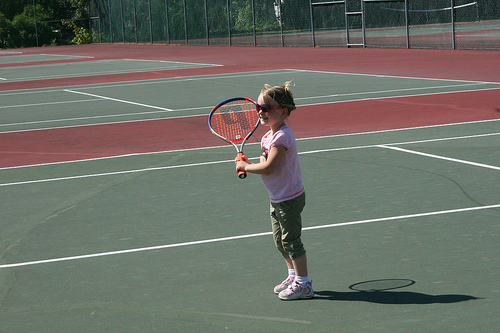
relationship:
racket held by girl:
[206, 97, 263, 179] [245, 70, 329, 305]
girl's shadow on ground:
[292, 267, 482, 316] [4, 39, 494, 324]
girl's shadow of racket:
[312, 289, 481, 305] [346, 259, 406, 292]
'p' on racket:
[215, 101, 255, 132] [206, 97, 263, 179]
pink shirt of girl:
[258, 123, 307, 220] [223, 77, 324, 306]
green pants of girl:
[264, 186, 318, 262] [224, 76, 335, 313]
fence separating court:
[33, 0, 500, 51] [0, 1, 500, 333]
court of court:
[0, 1, 500, 333] [12, 43, 492, 313]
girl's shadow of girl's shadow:
[312, 289, 481, 305] [312, 289, 481, 305]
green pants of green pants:
[268, 189, 307, 259] [268, 189, 307, 259]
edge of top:
[267, 183, 312, 206] [254, 134, 310, 204]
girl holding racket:
[234, 78, 316, 300] [206, 97, 263, 179]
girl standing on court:
[234, 78, 316, 300] [0, 1, 500, 333]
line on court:
[0, 201, 500, 269] [0, 1, 500, 333]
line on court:
[377, 144, 498, 174] [0, 1, 500, 333]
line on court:
[0, 129, 500, 186] [0, 1, 500, 333]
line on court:
[59, 85, 173, 111] [0, 1, 500, 333]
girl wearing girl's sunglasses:
[235, 74, 310, 299] [255, 103, 284, 112]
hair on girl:
[256, 79, 296, 122] [234, 78, 316, 300]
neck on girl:
[271, 115, 289, 133] [234, 78, 316, 300]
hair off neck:
[256, 79, 296, 122] [271, 115, 289, 133]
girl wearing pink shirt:
[234, 78, 316, 300] [259, 125, 305, 204]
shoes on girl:
[277, 281, 315, 301] [234, 78, 316, 300]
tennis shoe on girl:
[271, 270, 295, 300] [234, 78, 316, 300]